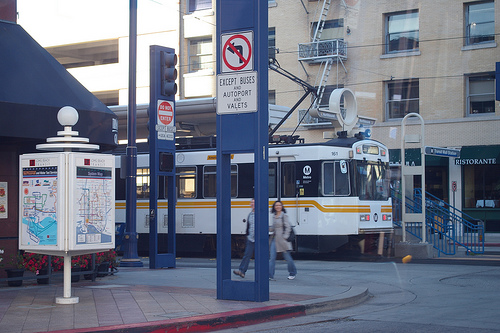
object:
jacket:
[267, 211, 294, 253]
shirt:
[245, 210, 257, 242]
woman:
[269, 201, 297, 282]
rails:
[339, 253, 500, 268]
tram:
[108, 137, 393, 260]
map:
[75, 176, 111, 246]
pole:
[63, 251, 73, 298]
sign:
[219, 30, 255, 74]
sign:
[213, 67, 262, 115]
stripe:
[116, 198, 393, 213]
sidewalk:
[1, 265, 380, 333]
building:
[49, 2, 500, 259]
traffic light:
[160, 52, 181, 98]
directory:
[18, 105, 116, 306]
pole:
[125, 0, 142, 257]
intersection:
[283, 234, 499, 333]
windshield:
[354, 159, 391, 201]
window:
[381, 77, 422, 122]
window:
[462, 70, 499, 118]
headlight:
[359, 214, 366, 222]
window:
[462, 0, 499, 51]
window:
[184, 34, 215, 75]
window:
[183, 0, 214, 18]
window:
[267, 25, 276, 70]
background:
[0, 0, 500, 252]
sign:
[156, 99, 175, 127]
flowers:
[35, 263, 41, 268]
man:
[231, 199, 257, 280]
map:
[20, 175, 58, 246]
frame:
[210, 0, 276, 304]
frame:
[145, 44, 184, 269]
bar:
[401, 112, 428, 244]